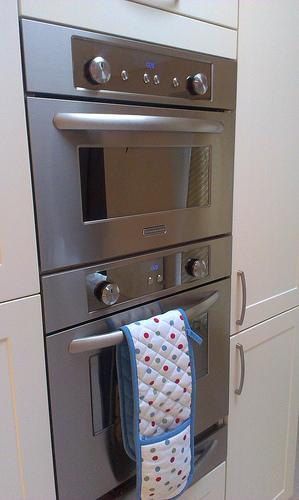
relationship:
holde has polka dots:
[108, 319, 181, 433] [151, 346, 174, 385]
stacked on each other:
[24, 53, 249, 486] [152, 33, 251, 267]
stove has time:
[60, 34, 270, 244] [144, 61, 156, 72]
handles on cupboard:
[232, 250, 259, 319] [228, 0, 298, 337]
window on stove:
[69, 137, 224, 215] [60, 34, 270, 244]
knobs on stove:
[45, 52, 226, 96] [60, 34, 270, 244]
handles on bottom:
[232, 250, 259, 319] [104, 433, 235, 490]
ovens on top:
[69, 137, 224, 215] [1, 50, 255, 291]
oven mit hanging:
[60, 34, 270, 244] [86, 304, 195, 372]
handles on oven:
[23, 89, 231, 146] [60, 34, 270, 244]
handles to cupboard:
[231, 329, 265, 395] [187, 36, 278, 393]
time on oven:
[134, 56, 168, 80] [60, 34, 270, 244]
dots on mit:
[160, 324, 181, 348] [121, 256, 212, 482]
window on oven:
[69, 137, 224, 215] [60, 34, 270, 244]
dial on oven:
[172, 62, 225, 98] [27, 97, 240, 204]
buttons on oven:
[117, 68, 189, 92] [27, 97, 240, 204]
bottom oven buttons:
[104, 433, 235, 490] [134, 261, 182, 295]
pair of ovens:
[24, 53, 249, 486] [60, 34, 270, 244]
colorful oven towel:
[133, 357, 202, 459] [137, 233, 233, 410]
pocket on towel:
[112, 402, 222, 493] [137, 233, 233, 410]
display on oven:
[120, 63, 171, 88] [27, 97, 240, 204]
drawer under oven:
[175, 455, 234, 499] [27, 97, 240, 204]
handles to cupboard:
[232, 250, 259, 319] [228, 0, 298, 337]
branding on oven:
[109, 210, 178, 252] [27, 97, 240, 204]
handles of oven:
[232, 250, 259, 319] [27, 97, 240, 204]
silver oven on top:
[60, 34, 270, 244] [30, 21, 250, 120]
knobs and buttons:
[45, 52, 226, 96] [117, 68, 189, 92]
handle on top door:
[23, 89, 231, 146] [27, 97, 240, 204]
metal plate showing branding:
[109, 210, 178, 252] [140, 222, 166, 238]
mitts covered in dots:
[121, 256, 212, 482] [160, 324, 181, 348]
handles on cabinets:
[231, 329, 265, 395] [213, 25, 286, 234]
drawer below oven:
[175, 455, 234, 499] [27, 97, 240, 204]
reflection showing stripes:
[174, 155, 220, 192] [142, 146, 226, 215]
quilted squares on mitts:
[155, 335, 178, 365] [121, 256, 212, 482]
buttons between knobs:
[117, 68, 189, 92] [45, 52, 226, 96]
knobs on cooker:
[88, 52, 112, 86] [60, 34, 270, 244]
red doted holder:
[138, 329, 155, 346] [121, 256, 212, 482]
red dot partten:
[138, 329, 155, 346] [137, 324, 186, 390]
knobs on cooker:
[88, 52, 112, 86] [1, 50, 255, 291]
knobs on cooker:
[88, 52, 112, 86] [126, 96, 250, 217]